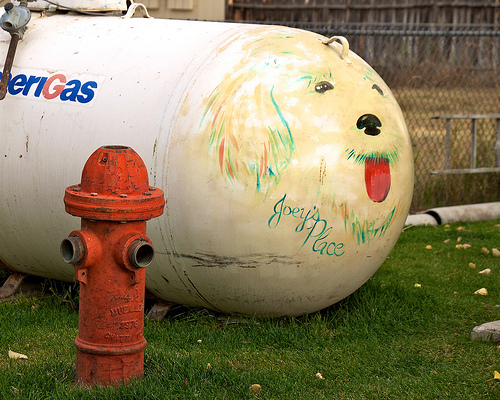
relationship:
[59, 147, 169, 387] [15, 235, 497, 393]
fire hydrant on grass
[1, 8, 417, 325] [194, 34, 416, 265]
gas tank has drawing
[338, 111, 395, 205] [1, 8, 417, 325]
paint on gas tank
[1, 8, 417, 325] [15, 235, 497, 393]
gas tank on grass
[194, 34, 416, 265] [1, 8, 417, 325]
drawing on gas tank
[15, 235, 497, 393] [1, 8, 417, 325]
grass around gas tank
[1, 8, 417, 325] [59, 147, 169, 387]
gas tank behind fire hydrant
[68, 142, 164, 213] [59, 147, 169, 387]
cap on fire hydrant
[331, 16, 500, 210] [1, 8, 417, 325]
fence behind gas tank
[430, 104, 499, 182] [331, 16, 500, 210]
ladder on fence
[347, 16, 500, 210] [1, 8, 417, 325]
fence behind gas tank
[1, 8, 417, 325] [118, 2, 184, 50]
gas tank has handle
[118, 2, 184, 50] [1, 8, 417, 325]
handle on gas tank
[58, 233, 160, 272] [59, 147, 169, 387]
outlet on fire hydrant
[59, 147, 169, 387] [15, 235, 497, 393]
fire hydrant in grass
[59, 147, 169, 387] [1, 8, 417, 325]
fire hydrant near gas tank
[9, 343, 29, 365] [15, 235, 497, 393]
leaf on grass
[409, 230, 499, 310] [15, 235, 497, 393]
leaves on grass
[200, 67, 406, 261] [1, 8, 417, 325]
drawing on gas tank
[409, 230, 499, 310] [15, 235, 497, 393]
leaves in grass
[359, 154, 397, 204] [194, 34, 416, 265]
tongue on drawing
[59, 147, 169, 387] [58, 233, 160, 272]
fire hydrant has outlet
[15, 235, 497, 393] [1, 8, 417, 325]
grass under gas tank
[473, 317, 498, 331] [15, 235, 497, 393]
rock on grass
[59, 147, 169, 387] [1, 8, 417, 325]
fire hydrant in front of gas tank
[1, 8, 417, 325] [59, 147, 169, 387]
gas tank by fire hydrant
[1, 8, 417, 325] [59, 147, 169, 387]
gas tank near fire hydrant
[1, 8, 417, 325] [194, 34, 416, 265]
gas tank with drawing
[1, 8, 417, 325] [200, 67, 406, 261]
gas tank has drawing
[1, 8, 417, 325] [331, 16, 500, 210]
gas tank near fence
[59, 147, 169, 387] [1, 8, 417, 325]
fire hydrant next to gas tank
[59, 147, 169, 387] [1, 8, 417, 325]
fire hydrant by gas tank